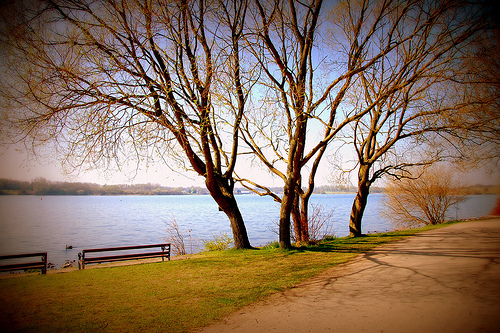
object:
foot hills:
[25, 176, 209, 196]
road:
[196, 211, 500, 332]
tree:
[376, 165, 480, 229]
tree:
[0, 0, 257, 248]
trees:
[6, 173, 207, 204]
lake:
[0, 190, 500, 266]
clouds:
[2, 88, 494, 188]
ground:
[187, 213, 500, 333]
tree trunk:
[337, 160, 379, 242]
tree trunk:
[271, 159, 309, 246]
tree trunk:
[288, 183, 312, 243]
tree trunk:
[199, 170, 251, 248]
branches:
[188, 0, 223, 185]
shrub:
[203, 231, 235, 255]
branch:
[47, 108, 209, 176]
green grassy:
[0, 236, 300, 331]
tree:
[342, 3, 497, 243]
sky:
[0, 0, 497, 195]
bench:
[1, 251, 47, 275]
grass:
[0, 215, 459, 333]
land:
[0, 217, 497, 333]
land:
[0, 171, 498, 196]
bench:
[77, 239, 170, 269]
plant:
[156, 209, 192, 256]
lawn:
[0, 214, 484, 331]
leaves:
[54, 27, 91, 56]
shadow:
[363, 239, 500, 302]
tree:
[223, 0, 353, 255]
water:
[0, 167, 500, 260]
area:
[0, 178, 500, 333]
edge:
[184, 295, 263, 333]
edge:
[82, 242, 172, 253]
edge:
[80, 180, 172, 196]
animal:
[65, 243, 73, 249]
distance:
[0, 168, 500, 199]